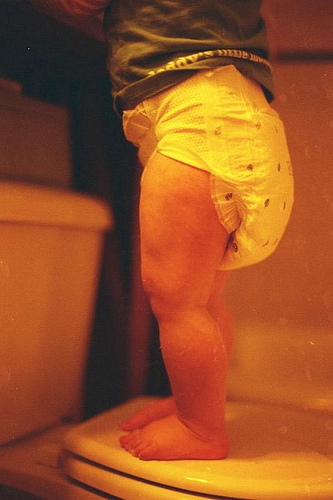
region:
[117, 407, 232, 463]
baby's left foot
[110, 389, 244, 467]
baby's tiny feet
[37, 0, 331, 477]
lower half of baby standing on toilet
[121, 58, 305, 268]
baby's white and spotted diaper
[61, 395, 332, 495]
white porcelin toilet seat lid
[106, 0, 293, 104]
part of baby's green tshirt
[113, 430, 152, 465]
five toes on baby's foot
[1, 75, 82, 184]
blurry tissue box on toilet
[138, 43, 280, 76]
white writing on baby's tshirt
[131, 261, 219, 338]
baby's left knee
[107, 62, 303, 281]
a toddler wearing a diaper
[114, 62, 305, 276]
diaper is white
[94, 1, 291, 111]
part of a shirt color gray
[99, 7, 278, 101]
shirt has white letters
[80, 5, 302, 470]
toddler is barefoot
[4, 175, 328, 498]
a toilet color white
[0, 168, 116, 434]
water tank of a toilet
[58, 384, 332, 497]
lid of toilet is plastic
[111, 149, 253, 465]
legs of toddler are pink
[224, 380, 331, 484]
shadow cast on toilet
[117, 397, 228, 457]
pudgy feet of baby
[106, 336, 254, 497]
feet on a toilet seat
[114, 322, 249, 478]
feet on the lid of a toilet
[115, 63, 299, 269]
disposable diaper in use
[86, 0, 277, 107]
green shirt on the baby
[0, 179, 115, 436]
toilet tank of the toilet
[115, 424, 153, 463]
toes on a baby's foot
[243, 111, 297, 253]
spots on a disposable diaper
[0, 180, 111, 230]
lid of a toilet tank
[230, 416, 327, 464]
shadow of the baby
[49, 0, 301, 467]
a baby stand on a toilet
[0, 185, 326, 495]
a white toilet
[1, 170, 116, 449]
tank of a toilet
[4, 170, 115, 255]
lid of toilet is white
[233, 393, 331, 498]
shadow cast on lid of toilet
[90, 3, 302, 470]
a toddler wearing a diaper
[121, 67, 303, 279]
diaper is color white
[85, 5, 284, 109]
toddler wearing a gray tee short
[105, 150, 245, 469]
feet of toddler are short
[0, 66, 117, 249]
a box of tissues on a tank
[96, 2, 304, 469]
this is a child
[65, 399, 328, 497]
the child is standing on a toilet board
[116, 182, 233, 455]
the leg of a child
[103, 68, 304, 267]
the child is wearing diapers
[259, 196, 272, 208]
a pattern on the diaper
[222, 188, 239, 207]
a pattern on the diaper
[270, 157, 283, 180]
a pattern on the diaper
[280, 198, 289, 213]
a pattern on the diaper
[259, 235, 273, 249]
a pattern on the diaper